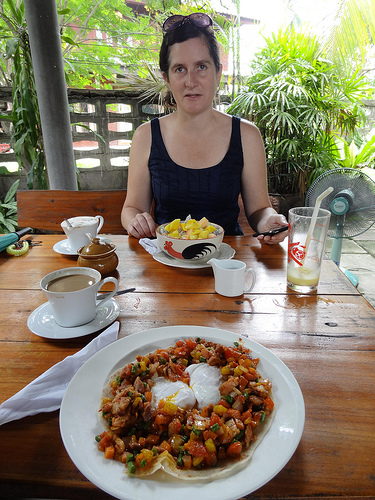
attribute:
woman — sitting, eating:
[134, 19, 257, 231]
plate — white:
[134, 248, 219, 269]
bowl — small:
[153, 225, 222, 262]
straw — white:
[315, 192, 333, 215]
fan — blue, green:
[315, 151, 368, 249]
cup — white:
[50, 303, 118, 332]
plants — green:
[66, 23, 129, 82]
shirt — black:
[138, 181, 262, 197]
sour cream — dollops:
[71, 221, 96, 235]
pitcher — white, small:
[42, 210, 91, 246]